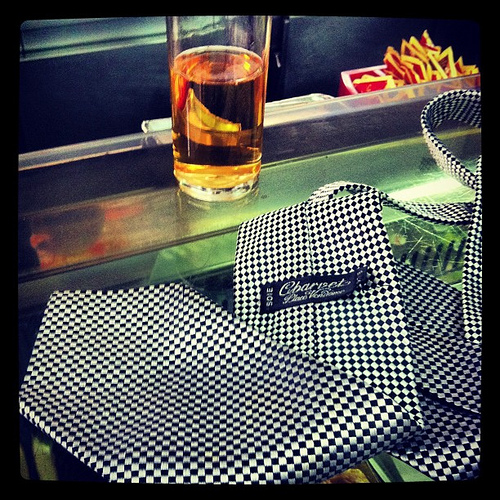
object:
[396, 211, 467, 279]
scratches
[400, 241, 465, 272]
black writing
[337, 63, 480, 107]
box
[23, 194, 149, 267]
reflection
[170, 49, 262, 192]
beverage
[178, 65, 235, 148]
reflection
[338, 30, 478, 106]
packets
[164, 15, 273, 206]
clear glass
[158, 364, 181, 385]
design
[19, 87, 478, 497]
cloth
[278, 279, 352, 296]
lettering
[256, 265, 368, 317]
tag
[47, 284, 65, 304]
tip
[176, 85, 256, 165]
shadow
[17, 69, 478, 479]
counter